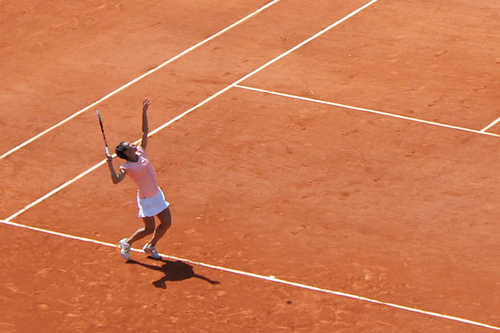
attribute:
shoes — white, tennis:
[116, 239, 158, 263]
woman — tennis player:
[99, 102, 174, 259]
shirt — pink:
[112, 155, 162, 194]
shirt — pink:
[126, 165, 166, 197]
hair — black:
[108, 140, 140, 168]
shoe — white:
[139, 245, 163, 262]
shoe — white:
[119, 239, 130, 263]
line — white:
[251, 65, 498, 170]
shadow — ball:
[285, 296, 291, 306]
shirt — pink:
[118, 144, 158, 198]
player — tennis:
[89, 91, 178, 268]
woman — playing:
[103, 95, 172, 261]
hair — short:
[114, 144, 124, 156]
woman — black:
[98, 140, 180, 261]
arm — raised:
[135, 95, 160, 154]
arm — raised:
[102, 152, 129, 183]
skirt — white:
[136, 185, 170, 217]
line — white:
[23, 218, 499, 331]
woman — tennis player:
[87, 93, 198, 268]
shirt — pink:
[117, 142, 169, 201]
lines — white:
[2, 2, 497, 331]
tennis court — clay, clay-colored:
[4, 2, 498, 331]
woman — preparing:
[79, 87, 189, 273]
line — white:
[5, 4, 265, 156]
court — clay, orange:
[2, 0, 499, 330]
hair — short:
[114, 133, 125, 160]